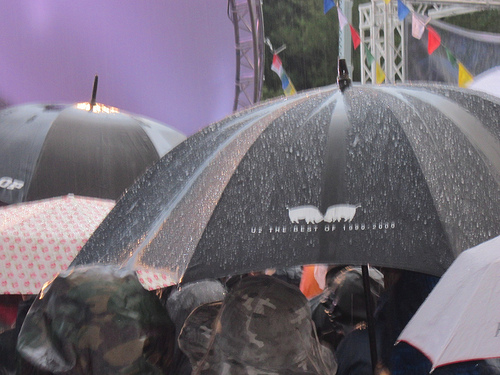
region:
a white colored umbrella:
[446, 293, 466, 318]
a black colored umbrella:
[228, 165, 246, 205]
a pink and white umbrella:
[18, 216, 50, 243]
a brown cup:
[228, 298, 302, 353]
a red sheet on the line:
[418, 24, 445, 56]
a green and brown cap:
[43, 299, 115, 374]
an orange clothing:
[301, 275, 319, 292]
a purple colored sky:
[172, 76, 189, 99]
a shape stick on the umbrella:
[74, 60, 120, 118]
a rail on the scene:
[224, 37, 271, 92]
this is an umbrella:
[54, 32, 492, 314]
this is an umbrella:
[389, 223, 498, 371]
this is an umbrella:
[0, 77, 192, 204]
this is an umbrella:
[0, 192, 114, 296]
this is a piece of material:
[455, 50, 481, 99]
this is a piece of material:
[420, 23, 445, 65]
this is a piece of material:
[393, 5, 414, 27]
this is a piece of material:
[369, 57, 394, 93]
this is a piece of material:
[264, 51, 285, 82]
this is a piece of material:
[340, 23, 372, 56]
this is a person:
[25, 268, 132, 369]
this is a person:
[175, 269, 333, 371]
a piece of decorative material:
[407, 26, 454, 56]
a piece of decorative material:
[54, 263, 158, 363]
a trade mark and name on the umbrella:
[256, 190, 366, 240]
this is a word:
[240, 215, 310, 260]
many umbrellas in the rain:
[5, 61, 497, 365]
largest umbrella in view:
[103, 88, 499, 288]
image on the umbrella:
[276, 191, 363, 226]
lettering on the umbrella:
[233, 222, 405, 239]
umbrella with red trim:
[394, 205, 497, 373]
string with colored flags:
[323, 3, 478, 90]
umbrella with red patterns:
[3, 187, 113, 305]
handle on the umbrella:
[356, 268, 396, 374]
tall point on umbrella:
[74, 67, 106, 107]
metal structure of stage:
[339, 3, 420, 82]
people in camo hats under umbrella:
[34, 264, 333, 374]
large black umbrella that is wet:
[112, 70, 490, 285]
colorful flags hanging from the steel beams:
[313, 1, 481, 92]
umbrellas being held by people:
[2, 69, 495, 369]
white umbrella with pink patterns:
[0, 185, 123, 297]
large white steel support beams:
[332, 4, 491, 87]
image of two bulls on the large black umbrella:
[273, 198, 377, 235]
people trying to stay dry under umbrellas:
[11, 265, 393, 373]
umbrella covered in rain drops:
[94, 80, 492, 271]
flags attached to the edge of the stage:
[261, 37, 305, 109]